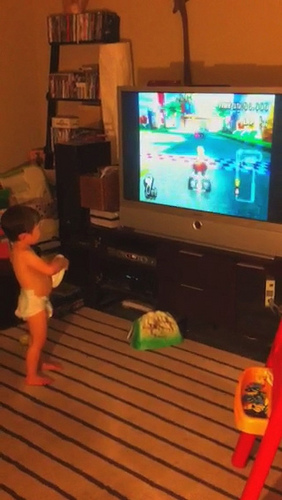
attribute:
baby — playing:
[0, 196, 67, 384]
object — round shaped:
[188, 218, 202, 234]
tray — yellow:
[231, 363, 280, 437]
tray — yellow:
[234, 362, 273, 434]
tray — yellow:
[235, 362, 279, 434]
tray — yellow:
[233, 367, 270, 433]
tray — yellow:
[234, 366, 275, 432]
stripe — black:
[65, 307, 250, 380]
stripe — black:
[52, 311, 242, 386]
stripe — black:
[46, 321, 238, 398]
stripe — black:
[2, 330, 241, 433]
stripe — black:
[1, 379, 255, 499]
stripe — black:
[1, 401, 196, 498]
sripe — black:
[1, 424, 129, 498]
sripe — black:
[1, 451, 75, 498]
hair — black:
[1, 203, 46, 240]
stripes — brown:
[64, 377, 186, 462]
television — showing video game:
[113, 84, 281, 259]